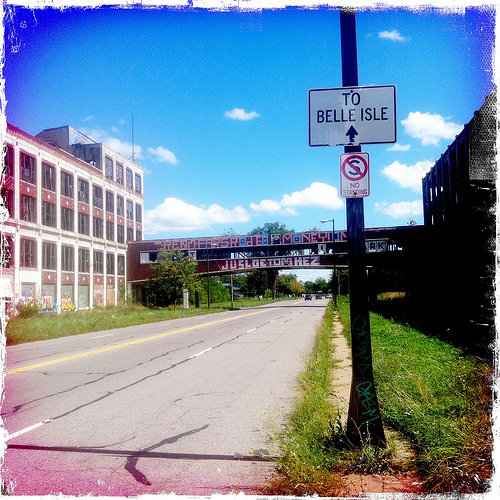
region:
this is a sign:
[308, 85, 396, 145]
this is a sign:
[339, 152, 369, 196]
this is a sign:
[218, 256, 335, 268]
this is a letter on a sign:
[341, 90, 353, 106]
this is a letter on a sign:
[350, 91, 362, 105]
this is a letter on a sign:
[316, 105, 323, 127]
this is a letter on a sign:
[380, 103, 389, 121]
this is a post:
[308, 42, 403, 450]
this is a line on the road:
[6, 350, 45, 375]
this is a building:
[6, 123, 146, 306]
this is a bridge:
[112, 211, 476, 290]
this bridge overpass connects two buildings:
[75, 120, 485, 312]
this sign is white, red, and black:
[322, 141, 393, 204]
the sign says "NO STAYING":
[332, 150, 389, 202]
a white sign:
[290, 76, 435, 161]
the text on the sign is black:
[296, 80, 418, 157]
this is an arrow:
[337, 121, 363, 143]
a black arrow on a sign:
[335, 122, 365, 147]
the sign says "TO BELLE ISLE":
[293, 78, 433, 147]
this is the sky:
[161, 46, 194, 73]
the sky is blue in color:
[162, 56, 197, 85]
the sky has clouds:
[158, 184, 318, 221]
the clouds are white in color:
[174, 202, 199, 219]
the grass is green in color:
[384, 344, 421, 392]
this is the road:
[70, 349, 208, 439]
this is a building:
[12, 123, 156, 308]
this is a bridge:
[167, 239, 298, 266]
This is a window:
[16, 144, 41, 191]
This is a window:
[15, 234, 38, 274]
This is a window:
[38, 234, 60, 273]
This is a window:
[60, 239, 76, 274]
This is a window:
[59, 199, 79, 236]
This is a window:
[42, 163, 62, 190]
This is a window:
[74, 172, 92, 204]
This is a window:
[89, 180, 105, 208]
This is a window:
[91, 240, 108, 277]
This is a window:
[59, 270, 76, 310]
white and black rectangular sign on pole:
[301, 85, 401, 147]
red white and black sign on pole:
[337, 149, 374, 200]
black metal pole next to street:
[331, 3, 401, 450]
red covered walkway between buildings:
[122, 223, 470, 285]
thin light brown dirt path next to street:
[328, 295, 428, 499]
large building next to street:
[2, 111, 147, 322]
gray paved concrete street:
[1, 293, 335, 498]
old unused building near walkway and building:
[418, 88, 498, 335]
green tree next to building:
[146, 243, 206, 314]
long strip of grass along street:
[1, 289, 289, 348]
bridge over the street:
[127, 226, 460, 278]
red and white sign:
[340, 154, 372, 197]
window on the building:
[40, 164, 55, 189]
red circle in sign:
[337, 148, 369, 186]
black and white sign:
[306, 79, 401, 149]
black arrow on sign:
[338, 123, 365, 143]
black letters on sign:
[316, 84, 390, 130]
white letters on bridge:
[213, 251, 323, 279]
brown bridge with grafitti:
[123, 220, 425, 282]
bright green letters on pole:
[348, 374, 380, 431]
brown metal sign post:
[331, 11, 395, 460]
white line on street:
[3, 415, 46, 445]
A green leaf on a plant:
[168, 280, 170, 282]